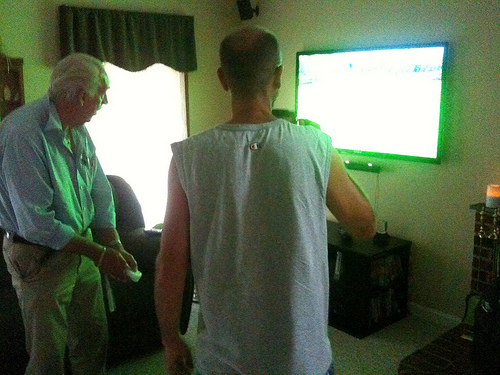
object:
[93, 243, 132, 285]
hand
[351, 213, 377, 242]
elbow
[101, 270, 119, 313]
strap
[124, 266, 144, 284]
nintendo wii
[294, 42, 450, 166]
screen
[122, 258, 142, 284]
controller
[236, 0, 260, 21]
black speaker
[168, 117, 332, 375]
shirt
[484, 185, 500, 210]
candle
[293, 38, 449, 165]
t.v.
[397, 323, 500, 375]
brick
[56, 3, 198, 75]
curtain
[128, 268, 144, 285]
game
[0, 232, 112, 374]
trouser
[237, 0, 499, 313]
wall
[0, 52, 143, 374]
man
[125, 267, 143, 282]
wii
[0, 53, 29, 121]
shelf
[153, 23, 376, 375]
man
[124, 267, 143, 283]
remote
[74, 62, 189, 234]
window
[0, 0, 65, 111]
wall